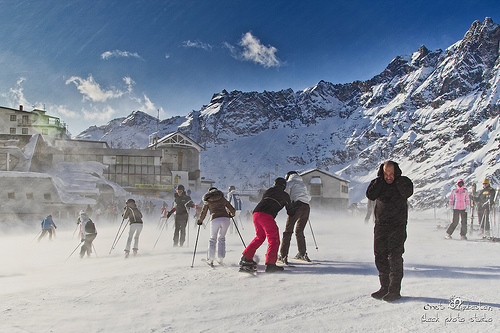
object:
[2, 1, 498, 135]
sky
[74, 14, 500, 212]
mountains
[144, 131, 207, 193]
building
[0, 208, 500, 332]
snow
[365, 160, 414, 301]
man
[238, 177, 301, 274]
man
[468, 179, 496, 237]
person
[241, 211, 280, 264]
pants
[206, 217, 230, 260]
pants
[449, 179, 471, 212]
jacket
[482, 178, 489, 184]
hat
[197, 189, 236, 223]
jacket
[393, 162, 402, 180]
gloves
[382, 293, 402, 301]
boots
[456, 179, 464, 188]
head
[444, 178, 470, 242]
body